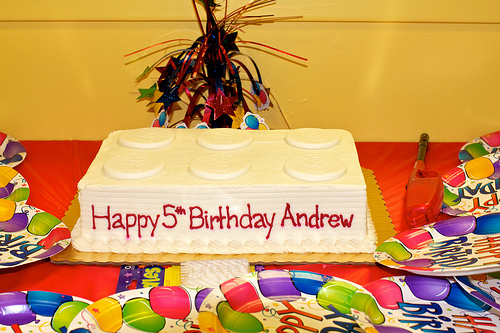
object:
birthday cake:
[69, 127, 378, 256]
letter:
[90, 203, 354, 240]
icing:
[78, 186, 366, 246]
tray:
[50, 168, 397, 266]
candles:
[116, 259, 252, 296]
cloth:
[0, 139, 465, 303]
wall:
[0, 0, 500, 142]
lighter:
[403, 133, 444, 228]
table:
[0, 137, 460, 329]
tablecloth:
[12, 140, 99, 214]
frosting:
[99, 147, 309, 185]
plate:
[0, 131, 499, 332]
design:
[68, 287, 200, 333]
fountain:
[121, 0, 309, 129]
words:
[423, 235, 479, 267]